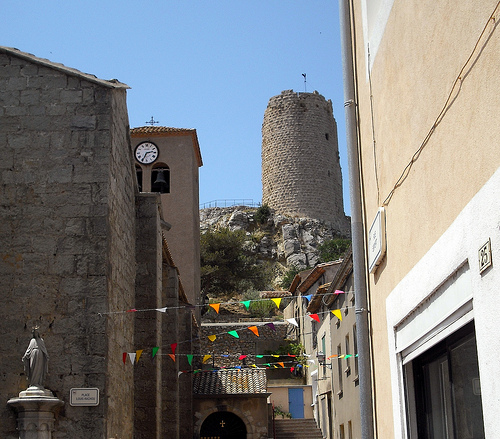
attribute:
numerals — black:
[138, 142, 154, 147]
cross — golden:
[215, 413, 232, 429]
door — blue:
[286, 382, 308, 416]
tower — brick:
[262, 88, 346, 232]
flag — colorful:
[124, 302, 137, 315]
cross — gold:
[141, 112, 164, 130]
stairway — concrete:
[265, 403, 320, 436]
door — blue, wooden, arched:
[281, 385, 315, 424]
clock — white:
[132, 137, 161, 166]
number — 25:
[464, 241, 494, 272]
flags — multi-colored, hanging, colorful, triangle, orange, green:
[291, 72, 314, 88]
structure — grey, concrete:
[22, 325, 59, 391]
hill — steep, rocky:
[227, 288, 278, 316]